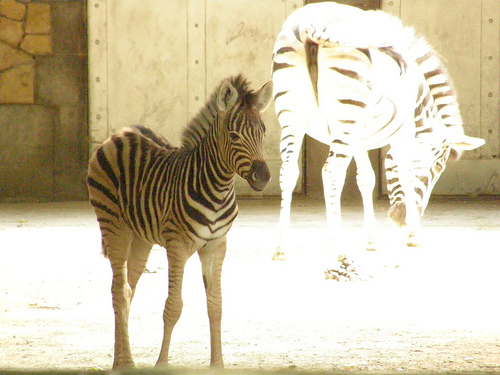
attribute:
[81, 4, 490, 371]
zebras — here, black, white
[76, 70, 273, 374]
zebra — black, white, grazing, standing, baby, young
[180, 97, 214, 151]
mane — black, white, fluffy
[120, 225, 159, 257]
underside — white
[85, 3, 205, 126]
door — white, big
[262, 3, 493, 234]
zebra — large, grazing, adult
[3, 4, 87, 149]
wall — stone, decorated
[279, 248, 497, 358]
road — dirty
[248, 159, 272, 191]
snout — black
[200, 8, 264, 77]
wall — white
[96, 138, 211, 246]
body — striped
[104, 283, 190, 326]
knees — knobby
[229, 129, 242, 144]
eye — black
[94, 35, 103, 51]
screws — metal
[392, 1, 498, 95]
door — smaller